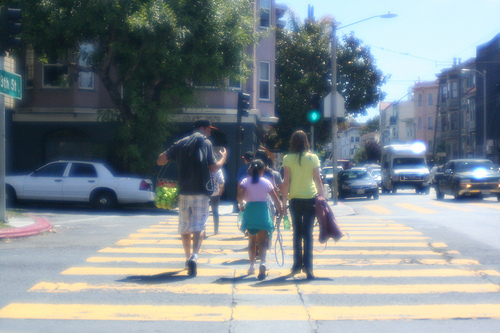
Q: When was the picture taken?
A: Daytime.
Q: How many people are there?
A: Five.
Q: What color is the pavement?
A: Gray.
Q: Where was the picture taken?
A: At an intersection on a busy street.